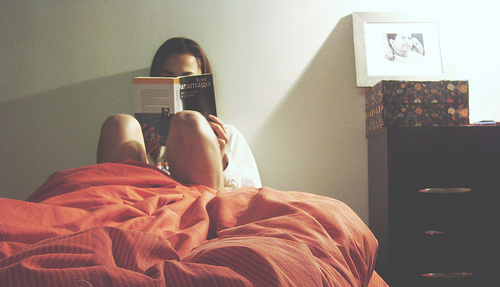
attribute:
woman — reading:
[98, 38, 263, 187]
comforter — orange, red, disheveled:
[0, 162, 380, 286]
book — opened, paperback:
[134, 74, 217, 143]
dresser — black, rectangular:
[366, 124, 498, 284]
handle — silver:
[418, 187, 471, 194]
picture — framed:
[353, 9, 458, 87]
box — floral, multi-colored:
[366, 81, 469, 129]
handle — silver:
[425, 271, 477, 277]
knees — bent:
[99, 109, 225, 189]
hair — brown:
[151, 36, 211, 75]